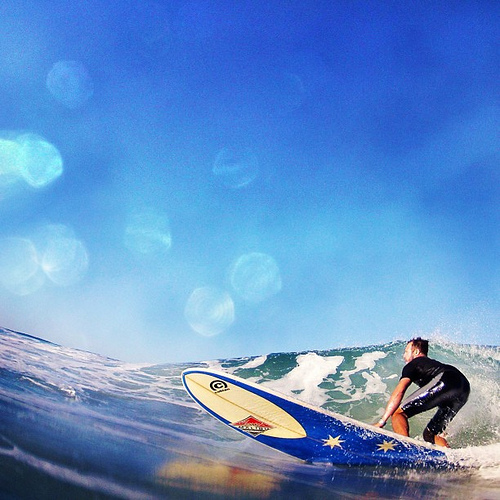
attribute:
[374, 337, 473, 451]
man — surfing, kneeling down, wet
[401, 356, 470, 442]
wetsuit — black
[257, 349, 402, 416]
foam — white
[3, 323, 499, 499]
ocean — blue, dark blue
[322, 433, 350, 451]
star — white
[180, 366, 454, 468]
surfboard — blue, print design, cream, white, yellow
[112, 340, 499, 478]
wave — whie, rising, splashing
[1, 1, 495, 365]
sky — clear bright blue, clear blue, blue, light blue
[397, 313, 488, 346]
splash — white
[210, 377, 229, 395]
logo — c